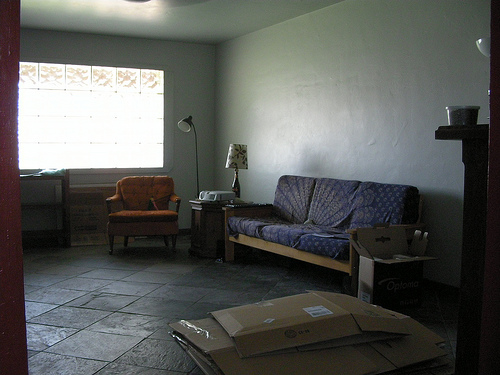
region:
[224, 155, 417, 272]
this is a chair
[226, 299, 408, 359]
this is a carton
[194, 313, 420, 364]
this is a carton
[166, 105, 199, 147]
this is a lamp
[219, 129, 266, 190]
this is a lamp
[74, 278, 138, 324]
this is a tile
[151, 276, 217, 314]
this is a tile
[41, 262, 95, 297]
this is a tile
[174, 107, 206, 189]
tall floor lamp that is off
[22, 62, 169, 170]
large glass block window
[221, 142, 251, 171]
lamp shade with floral pattern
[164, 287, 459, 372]
flattened out cardboard boxes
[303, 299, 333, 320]
shipping label on box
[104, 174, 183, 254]
vintage orange arm chair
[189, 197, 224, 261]
end table next to couch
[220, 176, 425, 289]
wooden futon with blue cover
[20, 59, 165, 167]
window is made of tiny squares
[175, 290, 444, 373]
pile of cardboard boxes on the floor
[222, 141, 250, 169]
lamp shade has leaves drawn on it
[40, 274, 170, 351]
floor is made of large square tiles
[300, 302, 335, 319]
white label on the cardboard box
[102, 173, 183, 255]
the chair is orange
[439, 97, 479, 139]
clear container sitting on a mantel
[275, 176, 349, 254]
blue cushions with golden patterns on it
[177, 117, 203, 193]
standing lamp in the corner of room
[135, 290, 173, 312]
tile on the floor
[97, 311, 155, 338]
tile on the floor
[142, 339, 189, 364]
tile on the floor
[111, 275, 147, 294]
tile on the floor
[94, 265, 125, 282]
tile on the floor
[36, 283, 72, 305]
tile on the floor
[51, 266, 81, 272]
tile on the floor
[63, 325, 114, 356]
tile on the floor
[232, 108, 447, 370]
a couch in a room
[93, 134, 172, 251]
a chair in a room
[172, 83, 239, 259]
a lamp in a room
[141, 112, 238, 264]
a tall lamp on the floor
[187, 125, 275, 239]
a lamp on a table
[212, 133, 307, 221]
a lamp on a side table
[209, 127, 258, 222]
a small lamp on the tabl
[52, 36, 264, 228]
a wall with a window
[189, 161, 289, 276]
a table next to the couch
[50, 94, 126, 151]
Daylight from a window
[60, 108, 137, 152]
Daylight from a window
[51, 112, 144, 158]
Daylight from a window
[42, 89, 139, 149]
Daylight from a window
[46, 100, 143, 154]
Daylight from a window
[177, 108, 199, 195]
a lamp in the room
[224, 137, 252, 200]
a shorter lamp in the room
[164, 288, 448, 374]
a pile of empty boxes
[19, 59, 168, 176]
the window on the wall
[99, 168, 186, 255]
the orange chair near lamp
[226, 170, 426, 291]
the couch near the lamp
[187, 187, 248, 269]
the end table near the couch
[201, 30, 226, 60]
the upper corner of the room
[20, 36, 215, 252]
far wall near center of photo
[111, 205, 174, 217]
seat of the chair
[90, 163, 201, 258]
orange chair by window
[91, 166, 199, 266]
orange chair by window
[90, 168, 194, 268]
orange chair by window